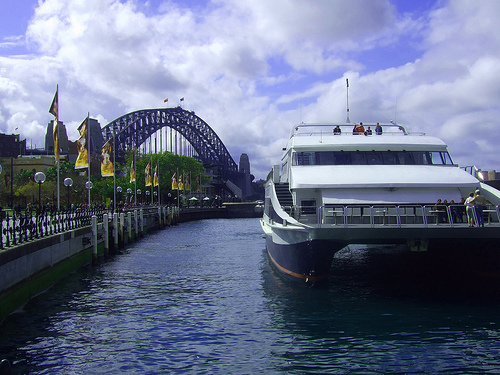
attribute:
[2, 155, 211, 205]
vegetation — green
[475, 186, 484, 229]
person — standing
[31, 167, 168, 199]
street lighting — next to sea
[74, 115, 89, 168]
flag — yellow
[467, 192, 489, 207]
shirt — yellow 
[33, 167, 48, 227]
lamp — round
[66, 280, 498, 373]
water — still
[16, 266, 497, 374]
sea — deep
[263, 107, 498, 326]
boat — white